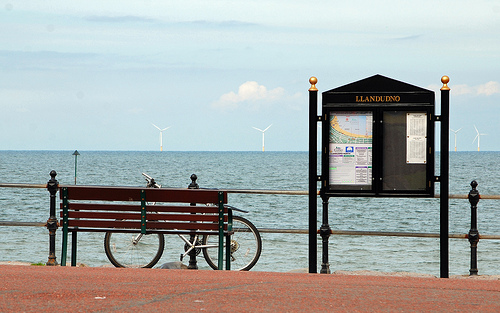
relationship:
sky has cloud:
[36, 14, 448, 148] [266, 81, 312, 118]